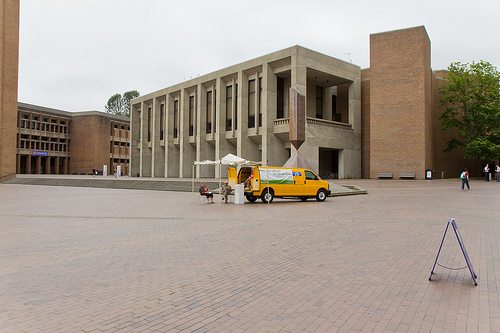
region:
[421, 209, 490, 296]
a sign on the ground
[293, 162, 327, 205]
a van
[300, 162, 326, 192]
van is yellow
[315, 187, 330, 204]
front tire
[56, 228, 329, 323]
the ground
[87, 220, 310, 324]
the ground is made of bricks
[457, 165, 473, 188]
a person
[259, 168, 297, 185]
sign on the van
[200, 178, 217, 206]
a person sitting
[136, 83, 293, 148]
a building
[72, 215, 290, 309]
The ground is made of concrete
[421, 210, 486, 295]
The sign standing on the ground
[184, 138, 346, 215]
The van is the color yellow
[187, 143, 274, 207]
The canopy covering the men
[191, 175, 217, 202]
The man is sitting down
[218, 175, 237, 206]
The man has on all gray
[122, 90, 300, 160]
The building is the color gray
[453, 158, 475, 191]
The person is wearing a backpack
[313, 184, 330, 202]
The front wheel of the tire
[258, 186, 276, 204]
The back wheel of the tire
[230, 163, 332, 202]
a large yellow van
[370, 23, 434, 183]
a large brown brick building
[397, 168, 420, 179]
a gray bench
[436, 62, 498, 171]
a tall green tree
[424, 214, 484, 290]
a purple sign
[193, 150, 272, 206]
a white tent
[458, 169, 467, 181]
a blue backpack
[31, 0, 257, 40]
part of a white sky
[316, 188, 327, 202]
the tire of a van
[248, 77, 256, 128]
a long window of a building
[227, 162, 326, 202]
yellow van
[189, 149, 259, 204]
white canopy tent behind yellow van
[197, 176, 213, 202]
person sitting under the tent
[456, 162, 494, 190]
people walking on walkway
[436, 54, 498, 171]
tree beside the building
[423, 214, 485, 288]
purple advertisement stand on walkway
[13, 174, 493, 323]
brick walkway around yellow van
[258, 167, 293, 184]
white and green banner on yellow van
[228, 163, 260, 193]
open back doors of yellow van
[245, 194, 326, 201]
black tires of yellow van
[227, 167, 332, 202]
the parked yellow van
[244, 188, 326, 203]
the wheels on the van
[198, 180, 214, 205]
the person sitting behind the van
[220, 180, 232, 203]
the person sitting behind the van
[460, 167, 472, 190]
the person walking in the background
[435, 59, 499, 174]
the tree in the background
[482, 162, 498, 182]
the people standing near the tree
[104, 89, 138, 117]
the tree behind the buildings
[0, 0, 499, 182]
the buildings behind the van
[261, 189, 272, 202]
the back wheel on the van